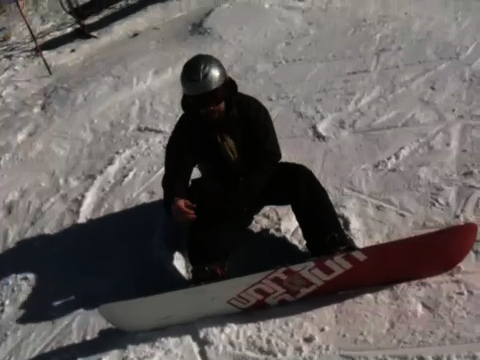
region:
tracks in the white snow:
[312, 44, 440, 183]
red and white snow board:
[87, 243, 477, 333]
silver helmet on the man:
[178, 52, 229, 97]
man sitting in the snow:
[118, 46, 336, 241]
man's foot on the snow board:
[288, 216, 384, 298]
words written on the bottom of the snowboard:
[233, 257, 364, 312]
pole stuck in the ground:
[24, 10, 57, 85]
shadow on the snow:
[5, 199, 156, 298]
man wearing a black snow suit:
[156, 98, 320, 251]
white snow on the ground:
[333, 27, 440, 156]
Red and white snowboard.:
[90, 247, 476, 347]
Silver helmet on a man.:
[169, 46, 246, 111]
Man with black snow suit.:
[168, 55, 367, 267]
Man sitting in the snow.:
[89, 44, 444, 318]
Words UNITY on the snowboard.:
[225, 262, 395, 317]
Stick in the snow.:
[6, 0, 71, 98]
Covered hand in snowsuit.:
[225, 168, 267, 209]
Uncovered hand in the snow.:
[171, 196, 203, 228]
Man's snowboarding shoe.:
[178, 255, 246, 286]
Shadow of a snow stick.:
[36, 0, 182, 19]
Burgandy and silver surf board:
[90, 222, 478, 335]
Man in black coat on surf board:
[94, 39, 478, 334]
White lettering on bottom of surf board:
[220, 245, 378, 310]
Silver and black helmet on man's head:
[178, 53, 235, 111]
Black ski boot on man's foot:
[191, 265, 227, 285]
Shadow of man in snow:
[1, 197, 316, 323]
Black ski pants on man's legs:
[177, 161, 345, 261]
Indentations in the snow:
[292, 327, 333, 359]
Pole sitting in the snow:
[8, 0, 59, 77]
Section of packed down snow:
[293, 7, 478, 162]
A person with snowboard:
[168, 17, 463, 298]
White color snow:
[344, 48, 419, 136]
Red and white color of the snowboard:
[103, 240, 478, 338]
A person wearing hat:
[182, 48, 239, 100]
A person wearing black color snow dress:
[190, 126, 296, 204]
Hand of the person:
[161, 186, 202, 228]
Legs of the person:
[228, 209, 347, 242]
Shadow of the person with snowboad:
[18, 225, 100, 359]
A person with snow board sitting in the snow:
[138, 46, 347, 276]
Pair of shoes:
[192, 240, 357, 283]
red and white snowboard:
[94, 233, 479, 334]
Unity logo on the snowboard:
[230, 245, 366, 316]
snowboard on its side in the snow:
[97, 220, 479, 335]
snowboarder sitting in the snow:
[165, 51, 370, 269]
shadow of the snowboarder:
[3, 195, 199, 327]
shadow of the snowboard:
[15, 325, 146, 359]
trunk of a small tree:
[1, 2, 68, 83]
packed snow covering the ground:
[6, 3, 477, 359]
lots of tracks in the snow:
[3, 1, 476, 357]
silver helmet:
[173, 53, 231, 98]